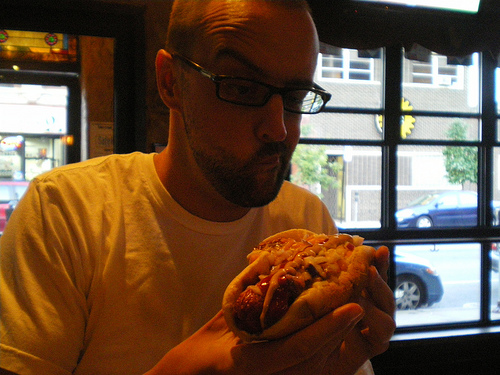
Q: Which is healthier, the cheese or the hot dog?
A: The cheese is healthier than the hot dog.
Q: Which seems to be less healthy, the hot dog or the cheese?
A: The hot dog is less healthy than the cheese.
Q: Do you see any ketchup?
A: Yes, there is ketchup.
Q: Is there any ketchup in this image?
A: Yes, there is ketchup.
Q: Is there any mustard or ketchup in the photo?
A: Yes, there is ketchup.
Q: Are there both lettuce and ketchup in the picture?
A: No, there is ketchup but no lettuce.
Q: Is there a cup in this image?
A: No, there are no cups.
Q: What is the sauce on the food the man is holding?
A: The sauce is ketchup.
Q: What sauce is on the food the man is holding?
A: The sauce is ketchup.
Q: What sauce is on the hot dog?
A: The sauce is ketchup.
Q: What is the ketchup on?
A: The ketchup is on the hot dog.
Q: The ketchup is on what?
A: The ketchup is on the hot dog.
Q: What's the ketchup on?
A: The ketchup is on the hot dog.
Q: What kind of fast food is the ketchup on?
A: The ketchup is on the hot dog.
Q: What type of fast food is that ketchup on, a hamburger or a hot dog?
A: The ketchup is on a hot dog.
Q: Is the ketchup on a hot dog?
A: Yes, the ketchup is on a hot dog.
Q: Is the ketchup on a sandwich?
A: No, the ketchup is on a hot dog.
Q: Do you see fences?
A: No, there are no fences.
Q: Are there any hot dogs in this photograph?
A: Yes, there is a hot dog.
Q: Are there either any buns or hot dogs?
A: Yes, there is a hot dog.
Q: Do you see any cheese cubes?
A: No, there are no cheese cubes.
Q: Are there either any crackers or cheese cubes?
A: No, there are no cheese cubes or crackers.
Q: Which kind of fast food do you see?
A: The fast food is a hot dog.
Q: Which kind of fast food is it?
A: The food is a hot dog.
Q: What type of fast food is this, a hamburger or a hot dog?
A: This is a hot dog.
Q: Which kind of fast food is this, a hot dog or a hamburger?
A: This is a hot dog.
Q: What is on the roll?
A: The hot dog is on the roll.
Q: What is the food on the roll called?
A: The food is a hot dog.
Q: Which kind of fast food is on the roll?
A: The food is a hot dog.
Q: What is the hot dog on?
A: The hot dog is on the roll.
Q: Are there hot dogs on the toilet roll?
A: Yes, there is a hot dog on the toilet roll.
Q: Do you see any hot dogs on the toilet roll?
A: Yes, there is a hot dog on the toilet roll.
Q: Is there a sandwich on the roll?
A: No, there is a hot dog on the roll.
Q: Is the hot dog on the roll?
A: Yes, the hot dog is on the roll.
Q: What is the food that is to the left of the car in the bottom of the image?
A: The food is a hot dog.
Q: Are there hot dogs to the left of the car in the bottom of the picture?
A: Yes, there is a hot dog to the left of the car.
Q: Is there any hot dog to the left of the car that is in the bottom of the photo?
A: Yes, there is a hot dog to the left of the car.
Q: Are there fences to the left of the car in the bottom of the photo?
A: No, there is a hot dog to the left of the car.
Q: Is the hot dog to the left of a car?
A: Yes, the hot dog is to the left of a car.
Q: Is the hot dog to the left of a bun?
A: No, the hot dog is to the left of a car.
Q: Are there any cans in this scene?
A: No, there are no cans.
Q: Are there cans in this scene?
A: No, there are no cans.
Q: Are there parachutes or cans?
A: No, there are no cans or parachutes.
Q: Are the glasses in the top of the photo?
A: Yes, the glasses are in the top of the image.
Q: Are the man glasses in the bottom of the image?
A: No, the glasses are in the top of the image.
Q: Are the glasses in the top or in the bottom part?
A: The glasses are in the top of the image.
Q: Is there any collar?
A: Yes, there is a collar.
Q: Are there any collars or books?
A: Yes, there is a collar.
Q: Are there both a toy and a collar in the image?
A: No, there is a collar but no toys.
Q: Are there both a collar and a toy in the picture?
A: No, there is a collar but no toys.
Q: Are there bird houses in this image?
A: No, there are no bird houses.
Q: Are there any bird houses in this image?
A: No, there are no bird houses.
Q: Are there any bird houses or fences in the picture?
A: No, there are no bird houses or fences.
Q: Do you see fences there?
A: No, there are no fences.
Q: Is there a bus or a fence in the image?
A: No, there are no fences or buses.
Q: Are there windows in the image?
A: Yes, there is a window.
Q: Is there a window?
A: Yes, there is a window.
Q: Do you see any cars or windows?
A: Yes, there is a window.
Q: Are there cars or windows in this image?
A: Yes, there is a window.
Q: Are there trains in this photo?
A: No, there are no trains.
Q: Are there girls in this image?
A: No, there are no girls.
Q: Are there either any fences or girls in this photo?
A: No, there are no girls or fences.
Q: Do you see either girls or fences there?
A: No, there are no girls or fences.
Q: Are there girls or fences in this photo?
A: No, there are no girls or fences.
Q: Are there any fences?
A: No, there are no fences.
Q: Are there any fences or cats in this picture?
A: No, there are no fences or cats.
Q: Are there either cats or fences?
A: No, there are no fences or cats.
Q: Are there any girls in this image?
A: No, there are no girls.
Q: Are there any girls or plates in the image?
A: No, there are no girls or plates.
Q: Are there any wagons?
A: No, there are no wagons.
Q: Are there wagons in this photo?
A: No, there are no wagons.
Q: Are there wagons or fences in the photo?
A: No, there are no wagons or fences.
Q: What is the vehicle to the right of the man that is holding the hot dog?
A: The vehicle is a car.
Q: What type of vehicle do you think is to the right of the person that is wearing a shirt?
A: The vehicle is a car.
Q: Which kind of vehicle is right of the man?
A: The vehicle is a car.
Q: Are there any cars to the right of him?
A: Yes, there is a car to the right of the man.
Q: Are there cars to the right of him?
A: Yes, there is a car to the right of the man.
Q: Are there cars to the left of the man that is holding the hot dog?
A: No, the car is to the right of the man.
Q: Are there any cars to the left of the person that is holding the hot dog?
A: No, the car is to the right of the man.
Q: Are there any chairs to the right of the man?
A: No, there is a car to the right of the man.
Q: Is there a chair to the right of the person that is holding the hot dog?
A: No, there is a car to the right of the man.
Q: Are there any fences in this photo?
A: No, there are no fences.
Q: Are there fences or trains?
A: No, there are no fences or trains.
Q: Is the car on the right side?
A: Yes, the car is on the right of the image.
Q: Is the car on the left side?
A: No, the car is on the right of the image.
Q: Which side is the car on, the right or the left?
A: The car is on the right of the image.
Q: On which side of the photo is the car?
A: The car is on the right of the image.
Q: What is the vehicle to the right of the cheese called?
A: The vehicle is a car.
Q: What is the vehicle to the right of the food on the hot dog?
A: The vehicle is a car.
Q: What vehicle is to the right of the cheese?
A: The vehicle is a car.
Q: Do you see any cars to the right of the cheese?
A: Yes, there is a car to the right of the cheese.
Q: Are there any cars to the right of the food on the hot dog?
A: Yes, there is a car to the right of the cheese.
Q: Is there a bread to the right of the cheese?
A: No, there is a car to the right of the cheese.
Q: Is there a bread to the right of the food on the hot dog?
A: No, there is a car to the right of the cheese.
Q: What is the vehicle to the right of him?
A: The vehicle is a car.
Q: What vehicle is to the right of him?
A: The vehicle is a car.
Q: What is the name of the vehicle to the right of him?
A: The vehicle is a car.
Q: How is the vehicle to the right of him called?
A: The vehicle is a car.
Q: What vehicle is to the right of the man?
A: The vehicle is a car.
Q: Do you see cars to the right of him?
A: Yes, there is a car to the right of the man.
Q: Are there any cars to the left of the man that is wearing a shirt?
A: No, the car is to the right of the man.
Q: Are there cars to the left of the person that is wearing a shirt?
A: No, the car is to the right of the man.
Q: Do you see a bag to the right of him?
A: No, there is a car to the right of the man.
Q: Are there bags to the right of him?
A: No, there is a car to the right of the man.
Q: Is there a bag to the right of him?
A: No, there is a car to the right of the man.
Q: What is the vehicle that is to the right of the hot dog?
A: The vehicle is a car.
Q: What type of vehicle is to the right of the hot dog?
A: The vehicle is a car.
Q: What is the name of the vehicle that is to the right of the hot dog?
A: The vehicle is a car.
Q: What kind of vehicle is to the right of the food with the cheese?
A: The vehicle is a car.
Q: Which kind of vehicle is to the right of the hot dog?
A: The vehicle is a car.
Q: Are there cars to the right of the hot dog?
A: Yes, there is a car to the right of the hot dog.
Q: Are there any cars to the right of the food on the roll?
A: Yes, there is a car to the right of the hot dog.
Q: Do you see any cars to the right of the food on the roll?
A: Yes, there is a car to the right of the hot dog.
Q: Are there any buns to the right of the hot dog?
A: No, there is a car to the right of the hot dog.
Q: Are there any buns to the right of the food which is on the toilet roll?
A: No, there is a car to the right of the hot dog.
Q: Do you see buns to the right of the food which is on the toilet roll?
A: No, there is a car to the right of the hot dog.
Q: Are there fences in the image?
A: No, there are no fences.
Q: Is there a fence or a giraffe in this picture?
A: No, there are no fences or giraffes.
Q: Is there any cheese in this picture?
A: Yes, there is cheese.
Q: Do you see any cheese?
A: Yes, there is cheese.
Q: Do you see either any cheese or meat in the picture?
A: Yes, there is cheese.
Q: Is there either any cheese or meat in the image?
A: Yes, there is cheese.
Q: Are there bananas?
A: No, there are no bananas.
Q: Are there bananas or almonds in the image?
A: No, there are no bananas or almonds.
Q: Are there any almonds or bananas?
A: No, there are no bananas or almonds.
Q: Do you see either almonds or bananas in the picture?
A: No, there are no bananas or almonds.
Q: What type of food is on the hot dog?
A: The food is cheese.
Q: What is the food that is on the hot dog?
A: The food is cheese.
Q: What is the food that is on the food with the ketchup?
A: The food is cheese.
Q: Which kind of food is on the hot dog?
A: The food is cheese.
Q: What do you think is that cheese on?
A: The cheese is on the hot dog.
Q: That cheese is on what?
A: The cheese is on the hot dog.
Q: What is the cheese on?
A: The cheese is on the hot dog.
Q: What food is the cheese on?
A: The cheese is on the hot dog.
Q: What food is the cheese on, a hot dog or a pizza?
A: The cheese is on a hot dog.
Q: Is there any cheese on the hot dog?
A: Yes, there is cheese on the hot dog.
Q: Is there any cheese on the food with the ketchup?
A: Yes, there is cheese on the hot dog.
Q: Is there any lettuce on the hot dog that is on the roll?
A: No, there is cheese on the hot dog.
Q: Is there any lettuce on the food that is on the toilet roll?
A: No, there is cheese on the hot dog.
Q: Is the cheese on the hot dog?
A: Yes, the cheese is on the hot dog.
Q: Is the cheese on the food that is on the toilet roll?
A: Yes, the cheese is on the hot dog.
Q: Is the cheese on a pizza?
A: No, the cheese is on the hot dog.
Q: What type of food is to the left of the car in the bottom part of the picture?
A: The food is cheese.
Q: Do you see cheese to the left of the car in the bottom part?
A: Yes, there is cheese to the left of the car.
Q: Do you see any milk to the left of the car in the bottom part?
A: No, there is cheese to the left of the car.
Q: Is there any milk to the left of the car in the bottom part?
A: No, there is cheese to the left of the car.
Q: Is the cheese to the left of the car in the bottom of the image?
A: Yes, the cheese is to the left of the car.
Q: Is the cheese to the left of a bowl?
A: No, the cheese is to the left of the car.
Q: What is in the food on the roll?
A: The cheese is in the hot dog.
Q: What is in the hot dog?
A: The cheese is in the hot dog.